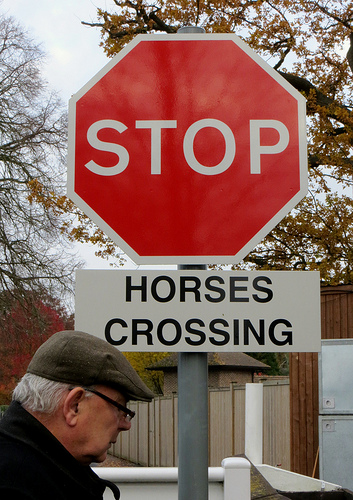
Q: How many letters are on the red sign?
A: Four.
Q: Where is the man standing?
A: Under sign.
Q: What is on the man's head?
A: Hat.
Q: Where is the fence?
A: Behind sign.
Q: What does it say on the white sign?
A: Horses Crossing.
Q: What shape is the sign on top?
A: Octogon.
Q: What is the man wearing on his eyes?
A: Glasses.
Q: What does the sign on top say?
A: STOP.